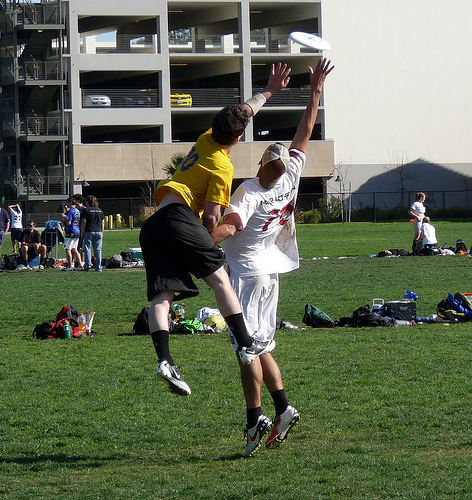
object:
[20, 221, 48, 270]
guy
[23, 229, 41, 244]
shirt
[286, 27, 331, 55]
frisbee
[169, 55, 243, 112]
second floor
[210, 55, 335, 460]
man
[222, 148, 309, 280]
white shirt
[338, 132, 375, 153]
sky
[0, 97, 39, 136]
stairs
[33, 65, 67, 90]
metal stairs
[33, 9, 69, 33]
metal stairs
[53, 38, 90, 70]
metal stairs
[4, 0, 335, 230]
parking garage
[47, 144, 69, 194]
door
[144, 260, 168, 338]
person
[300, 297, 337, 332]
bag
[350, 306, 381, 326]
bag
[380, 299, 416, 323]
bag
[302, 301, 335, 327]
bags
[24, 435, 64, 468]
ground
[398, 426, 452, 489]
ground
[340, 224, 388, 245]
ground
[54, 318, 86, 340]
bags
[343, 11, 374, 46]
sky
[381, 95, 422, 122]
ground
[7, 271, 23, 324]
person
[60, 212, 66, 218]
hands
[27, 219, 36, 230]
head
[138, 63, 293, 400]
man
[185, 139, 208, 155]
yellow car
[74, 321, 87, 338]
orange backpack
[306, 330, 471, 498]
open field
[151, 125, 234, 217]
tshirt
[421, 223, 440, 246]
shirt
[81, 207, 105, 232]
shirt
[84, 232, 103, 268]
jeans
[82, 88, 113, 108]
car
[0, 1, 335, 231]
garage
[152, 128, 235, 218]
shirt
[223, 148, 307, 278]
shirt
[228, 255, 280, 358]
shorts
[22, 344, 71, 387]
ground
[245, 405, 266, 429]
socks